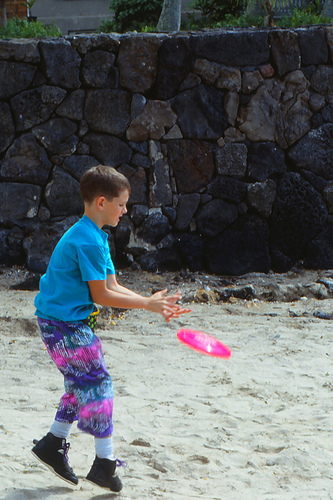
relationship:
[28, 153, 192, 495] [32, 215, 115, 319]
boy wearing shirt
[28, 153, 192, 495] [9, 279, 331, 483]
boy on beach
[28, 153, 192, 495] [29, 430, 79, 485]
boy wearing shoe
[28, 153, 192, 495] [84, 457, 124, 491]
boy wearing shoe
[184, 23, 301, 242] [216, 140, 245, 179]
wall made of rock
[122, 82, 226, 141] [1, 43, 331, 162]
bricks on wall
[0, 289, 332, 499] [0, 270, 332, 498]
sand on ground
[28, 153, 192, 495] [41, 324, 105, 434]
boy wearing pants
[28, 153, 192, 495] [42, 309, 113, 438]
boy wearing pants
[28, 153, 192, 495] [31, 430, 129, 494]
boy wearing shoes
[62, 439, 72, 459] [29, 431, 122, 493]
laces on black sneakers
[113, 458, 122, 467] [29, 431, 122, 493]
laces on black sneakers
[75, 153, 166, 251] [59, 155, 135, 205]
boy has hair cut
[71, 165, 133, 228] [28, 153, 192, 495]
head of a boy